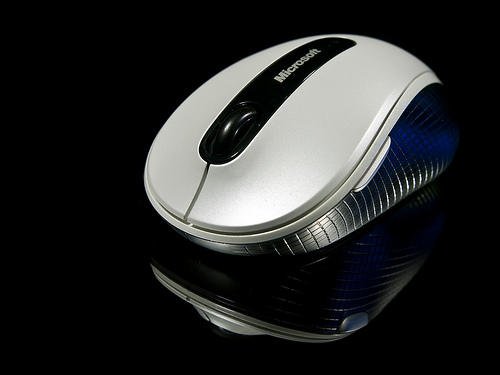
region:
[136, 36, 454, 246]
Mouse kept in the glass table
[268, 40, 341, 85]
Brand name of the mouse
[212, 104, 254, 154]
Scroll wheel of the mouse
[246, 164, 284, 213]
Left click button of the mouse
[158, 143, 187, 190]
Right click button of the mouse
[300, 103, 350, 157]
Plastic case of the mouse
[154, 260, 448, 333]
Reflection of the mouse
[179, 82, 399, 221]
Black and white color of the mouse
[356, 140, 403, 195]
Thumb button of the mouse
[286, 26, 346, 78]
Palm rest of the mouse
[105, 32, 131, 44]
this is the wall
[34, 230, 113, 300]
the wall is black in color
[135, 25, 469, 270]
this is a mouse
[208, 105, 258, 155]
this is a scroll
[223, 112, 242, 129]
the scroll is black in color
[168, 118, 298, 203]
these are two buttons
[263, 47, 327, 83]
these are some writings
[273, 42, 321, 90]
the writings are white in color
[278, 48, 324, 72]
the writings are small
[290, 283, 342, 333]
this is a reflection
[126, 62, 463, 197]
A black and white computer mouse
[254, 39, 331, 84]
A black and white microsoft mouse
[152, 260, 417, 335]
A black and white computer mouse's shaow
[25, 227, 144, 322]
A dark photo background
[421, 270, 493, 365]
A dark photo background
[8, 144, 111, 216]
A dark photo background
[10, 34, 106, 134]
A dark photo background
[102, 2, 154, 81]
A dark photo background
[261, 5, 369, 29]
A dark photo background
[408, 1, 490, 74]
A dark photo background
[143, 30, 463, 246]
a computer mouse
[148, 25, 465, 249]
a white and silver mouse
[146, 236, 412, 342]
the reflection of the mouse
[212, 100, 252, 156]
the dial on the mouse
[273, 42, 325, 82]
writing on the computer mouse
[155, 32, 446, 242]
a computer mouse with a black background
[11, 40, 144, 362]
the black background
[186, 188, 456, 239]
the bottom of the mouse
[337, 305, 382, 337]
a button on the mouse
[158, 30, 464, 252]
a computer mouse on a black desk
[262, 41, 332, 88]
The word "Microsoft" in silvery lettering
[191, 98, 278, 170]
A shiny black mouse wheel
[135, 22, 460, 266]
A futuristic-looking computer mouse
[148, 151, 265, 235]
The upper edge of the left and right buttons of a mouse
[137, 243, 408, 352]
The reflected image of a computer mouse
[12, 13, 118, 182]
A solid black background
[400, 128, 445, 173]
A glossy blue and black checked surface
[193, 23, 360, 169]
The black strip running over the top of a computer mouse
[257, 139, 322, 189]
A shiny white plastic surface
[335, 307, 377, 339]
A silver mouse "side" button